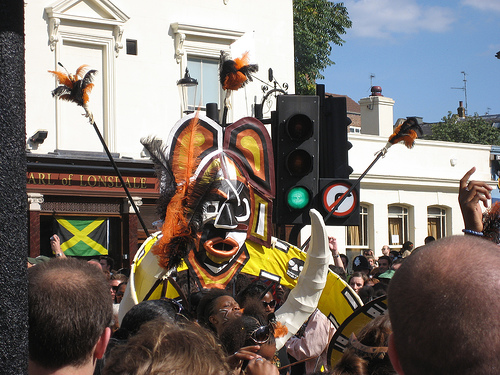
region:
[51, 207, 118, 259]
jamacian flag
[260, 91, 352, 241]
black street lights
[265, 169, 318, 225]
green go light on street light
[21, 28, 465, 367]
photograph taken on a busy street during parade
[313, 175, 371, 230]
round sign indicating no right turn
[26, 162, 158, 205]
name of business on door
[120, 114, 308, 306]
large costume with bright colors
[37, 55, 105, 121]
black ans orange feathers on costume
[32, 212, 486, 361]
large crowd of people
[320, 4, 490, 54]
small wispy clouds in sky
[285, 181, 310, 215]
green light on traffic signal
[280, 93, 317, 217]
black traffic signal on road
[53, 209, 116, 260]
black green and yellow flag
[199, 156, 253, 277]
mask on the face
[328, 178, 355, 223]
no right turn sign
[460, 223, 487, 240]
bracelet on person's wrist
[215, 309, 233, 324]
face paint on woman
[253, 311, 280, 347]
sunglasses on girl's head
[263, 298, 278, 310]
sunglasses on the woman's face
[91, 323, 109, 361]
the man's right ear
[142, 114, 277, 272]
Person wearing a colorful mask.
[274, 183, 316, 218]
Green light on traffic sign.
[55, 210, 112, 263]
Green, yellow, and black flag.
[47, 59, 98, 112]
Orange and black feathers.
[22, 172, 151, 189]
Gold writing on building.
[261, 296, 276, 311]
Sunglasses on woman's face.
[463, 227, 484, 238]
Bead bracelet on a person's wrist.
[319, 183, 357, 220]
A round red, white, and black street sign.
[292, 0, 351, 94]
Tall green tree next to building.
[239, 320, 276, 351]
Sunglasses on top of person's head.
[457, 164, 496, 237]
a hand with one finger upraised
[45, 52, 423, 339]
a mask and being held aloft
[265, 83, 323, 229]
a traffic light with green lit up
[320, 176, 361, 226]
no right turn sign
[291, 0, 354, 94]
a tree with green and yellow leaves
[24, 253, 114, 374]
the back of a man's balding head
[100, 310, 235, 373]
someone with light brown hair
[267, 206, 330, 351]
a fake white horn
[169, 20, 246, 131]
a white fancy edged window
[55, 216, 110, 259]
a green, yellow, and black flag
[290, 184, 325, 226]
Green light illuminated on traffic signal.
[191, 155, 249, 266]
Colorful mask in middle of street.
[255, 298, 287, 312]
Person wearing sunglasses on face.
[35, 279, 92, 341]
Person has dark hair.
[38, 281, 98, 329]
Person has short hair.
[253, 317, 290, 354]
Sunglasses on person's head.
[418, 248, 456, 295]
Person has short hair.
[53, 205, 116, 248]
Yellow, green, and black flag on building.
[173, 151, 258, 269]
a black and white mask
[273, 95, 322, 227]
it is a traffic light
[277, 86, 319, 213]
traffic green light in a pole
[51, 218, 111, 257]
black yellow and green flag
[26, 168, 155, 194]
golden letter on the wall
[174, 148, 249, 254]
brown and white mask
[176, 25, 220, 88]
frontal white window whit frame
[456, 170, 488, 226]
a right hand lifted up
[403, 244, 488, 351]
head with short hair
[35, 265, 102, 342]
head with short hair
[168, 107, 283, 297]
person wearing a colorful mask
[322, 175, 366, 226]
road sign with international "no" symbol